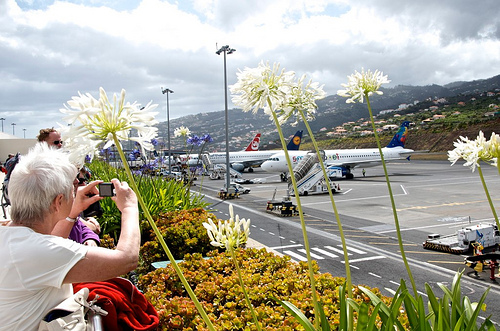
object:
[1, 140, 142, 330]
person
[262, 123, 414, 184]
airplane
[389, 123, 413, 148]
tail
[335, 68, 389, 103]
flowers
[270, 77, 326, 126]
flowers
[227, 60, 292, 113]
flowers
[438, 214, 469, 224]
paint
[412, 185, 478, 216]
asphalt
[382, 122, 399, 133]
houses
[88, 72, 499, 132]
hill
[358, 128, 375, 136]
houses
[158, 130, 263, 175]
airplane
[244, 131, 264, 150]
tail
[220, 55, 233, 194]
post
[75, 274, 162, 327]
jacket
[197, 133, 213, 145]
flower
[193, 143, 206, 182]
stems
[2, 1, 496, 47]
sky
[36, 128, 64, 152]
people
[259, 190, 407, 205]
lines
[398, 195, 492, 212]
lines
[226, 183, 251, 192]
car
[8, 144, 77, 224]
hair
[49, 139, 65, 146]
sunglasses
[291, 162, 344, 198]
truck